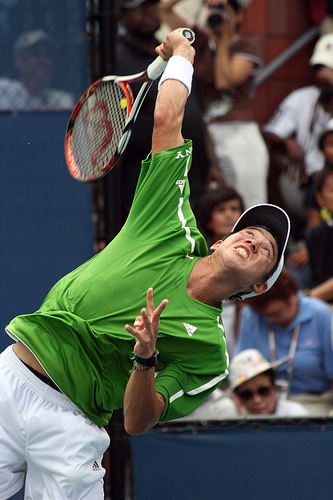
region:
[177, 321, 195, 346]
adidas logo on clothes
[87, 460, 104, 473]
adidas logo on clothes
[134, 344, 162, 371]
watch on man's wrist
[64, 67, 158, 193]
wilson racquet in hand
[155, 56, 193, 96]
armband on man's hand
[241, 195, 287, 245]
white hat on head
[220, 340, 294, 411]
spectator in the stands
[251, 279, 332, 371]
spectator in the stands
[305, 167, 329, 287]
spectator in the stands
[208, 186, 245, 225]
spectator in the stands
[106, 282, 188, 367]
tennis player has his hand up in the air flexing his fingers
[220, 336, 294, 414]
woman in audience wearing a hat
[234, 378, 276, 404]
woman in stands wearing sun glasses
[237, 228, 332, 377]
person in a blue shirt and has head down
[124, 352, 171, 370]
tennis player wearing a watch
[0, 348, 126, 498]
tennis player wearing white shorts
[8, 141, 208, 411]
tennis player wearing green shirt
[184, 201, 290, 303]
tennis player wearing a white hat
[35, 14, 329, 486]
tennis player has his hand extended trying to hit the ball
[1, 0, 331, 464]
many spectators are watching sitting in the bleachers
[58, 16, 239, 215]
The man is playing tennis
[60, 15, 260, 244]
He's reaching high for the ball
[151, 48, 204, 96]
Man is wearing a white wrist band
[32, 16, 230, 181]
Man is holding a tennis racket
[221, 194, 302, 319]
Man is wearing a white cap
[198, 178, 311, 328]
He looks like he's trying very hard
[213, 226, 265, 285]
The man is gritting his teeth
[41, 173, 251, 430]
The man is wearing a green shirt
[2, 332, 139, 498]
The man is wearing white shorts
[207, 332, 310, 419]
The woman is wearing a hat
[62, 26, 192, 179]
a red, white and black tennis racket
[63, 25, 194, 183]
a Wilson's tennis racket in the player's hand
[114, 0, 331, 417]
patrons in the stand watching the tennis player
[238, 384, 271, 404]
a woman wearing sunglasses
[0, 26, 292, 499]
a tennis player competing in tournament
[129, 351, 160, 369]
a sports watch on the man's left wrist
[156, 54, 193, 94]
a white wristband on the tennis player's right wrist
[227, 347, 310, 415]
a female patron watching the tennis player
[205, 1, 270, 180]
a woman taking a picture of the tennis player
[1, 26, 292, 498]
a tennis player swinging a racket to hit the ball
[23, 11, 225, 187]
tennis racquet in swing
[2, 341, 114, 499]
white tennis shorts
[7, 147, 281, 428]
man in a green shirt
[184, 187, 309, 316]
man making a strained face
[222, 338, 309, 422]
woman in hat and glasses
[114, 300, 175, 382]
watch on a man's wrist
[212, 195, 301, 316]
man wearing white hat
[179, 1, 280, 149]
person taking a photo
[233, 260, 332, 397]
spectator in blue shirt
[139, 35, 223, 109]
white wrist band